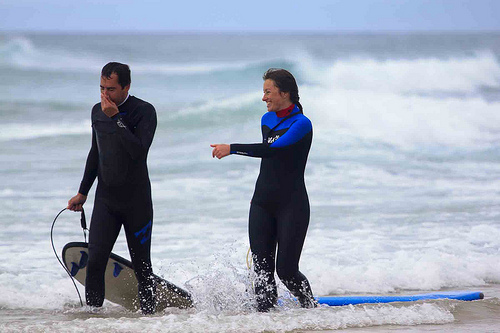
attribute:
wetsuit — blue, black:
[232, 104, 312, 316]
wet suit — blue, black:
[223, 61, 319, 312]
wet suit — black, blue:
[78, 95, 158, 307]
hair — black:
[101, 55, 131, 83]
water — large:
[404, 179, 454, 231]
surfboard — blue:
[271, 288, 487, 307]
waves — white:
[306, 54, 496, 178]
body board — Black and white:
[68, 237, 184, 319]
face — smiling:
[261, 78, 280, 113]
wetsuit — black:
[76, 90, 160, 319]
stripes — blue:
[131, 219, 153, 249]